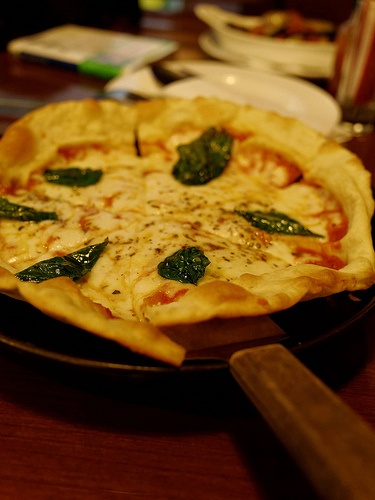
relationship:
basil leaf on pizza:
[16, 236, 110, 283] [0, 92, 374, 367]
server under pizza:
[153, 313, 374, 500] [0, 92, 374, 367]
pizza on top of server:
[0, 92, 374, 367] [153, 313, 374, 500]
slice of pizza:
[133, 94, 341, 217] [0, 92, 374, 367]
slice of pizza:
[1, 97, 147, 222] [0, 92, 374, 367]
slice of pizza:
[0, 186, 143, 290] [0, 92, 374, 367]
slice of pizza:
[0, 217, 186, 367] [0, 92, 374, 367]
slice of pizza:
[129, 213, 354, 329] [0, 92, 374, 367]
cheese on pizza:
[0, 130, 343, 326] [0, 92, 374, 367]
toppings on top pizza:
[1, 124, 352, 325] [0, 92, 374, 367]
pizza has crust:
[0, 92, 374, 367] [136, 96, 340, 178]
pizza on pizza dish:
[0, 92, 374, 367] [0, 286, 375, 404]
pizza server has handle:
[153, 313, 374, 500] [227, 343, 375, 499]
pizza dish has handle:
[0, 184, 375, 377] [227, 343, 375, 499]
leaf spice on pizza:
[41, 166, 103, 188] [0, 92, 374, 367]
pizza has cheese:
[0, 92, 374, 367] [0, 130, 343, 326]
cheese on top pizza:
[0, 130, 343, 326] [0, 92, 374, 367]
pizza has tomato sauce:
[0, 92, 374, 367] [1, 124, 350, 323]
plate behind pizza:
[155, 61, 342, 137] [0, 92, 374, 367]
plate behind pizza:
[197, 28, 336, 79] [0, 92, 374, 367]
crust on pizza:
[1, 94, 374, 370] [0, 92, 374, 367]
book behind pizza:
[6, 21, 180, 78] [0, 92, 374, 367]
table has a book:
[3, 0, 375, 499] [6, 21, 180, 78]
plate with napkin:
[155, 61, 342, 137] [158, 76, 308, 127]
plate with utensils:
[155, 61, 342, 137] [149, 62, 199, 88]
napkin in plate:
[158, 76, 308, 127] [155, 61, 342, 137]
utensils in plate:
[149, 62, 199, 88] [155, 61, 342, 137]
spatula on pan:
[153, 313, 374, 500] [0, 184, 375, 377]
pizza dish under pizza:
[0, 286, 375, 404] [0, 92, 374, 367]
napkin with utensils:
[158, 76, 308, 127] [149, 62, 199, 85]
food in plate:
[225, 8, 339, 46] [193, 4, 336, 77]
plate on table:
[155, 61, 342, 137] [3, 0, 375, 499]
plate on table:
[197, 28, 336, 79] [3, 0, 375, 499]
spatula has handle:
[153, 313, 374, 500] [227, 343, 375, 499]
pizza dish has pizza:
[0, 286, 375, 404] [0, 92, 374, 367]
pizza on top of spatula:
[0, 92, 374, 367] [153, 313, 374, 500]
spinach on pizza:
[158, 244, 211, 286] [0, 92, 374, 367]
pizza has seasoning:
[0, 92, 374, 367] [1, 124, 352, 325]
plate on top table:
[155, 61, 342, 137] [3, 0, 375, 499]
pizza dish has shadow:
[0, 286, 375, 404] [2, 319, 375, 438]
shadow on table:
[2, 319, 375, 438] [3, 0, 375, 499]